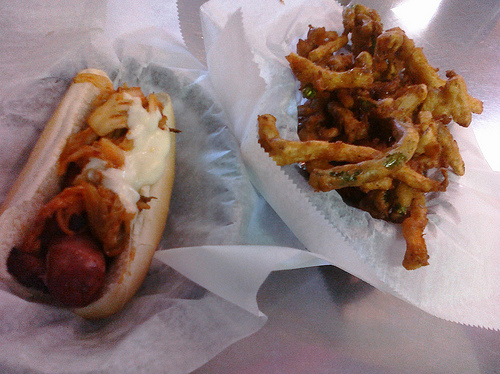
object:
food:
[278, 19, 454, 200]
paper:
[282, 189, 348, 250]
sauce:
[135, 138, 158, 170]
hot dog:
[11, 67, 177, 294]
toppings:
[74, 123, 119, 217]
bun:
[57, 94, 84, 134]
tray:
[189, 112, 244, 262]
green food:
[339, 154, 403, 188]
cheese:
[131, 134, 152, 167]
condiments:
[87, 116, 114, 218]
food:
[88, 91, 135, 133]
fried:
[357, 70, 426, 160]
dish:
[297, 188, 350, 235]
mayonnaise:
[138, 133, 162, 190]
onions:
[57, 194, 112, 242]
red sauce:
[29, 192, 121, 236]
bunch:
[314, 35, 420, 97]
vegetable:
[331, 81, 393, 147]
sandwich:
[63, 75, 173, 244]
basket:
[246, 148, 296, 202]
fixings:
[75, 170, 123, 237]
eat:
[70, 88, 152, 121]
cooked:
[44, 239, 98, 287]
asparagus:
[345, 24, 423, 92]